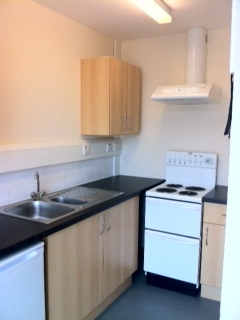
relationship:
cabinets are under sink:
[47, 193, 142, 320] [1, 198, 82, 225]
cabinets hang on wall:
[80, 56, 141, 136] [1, 2, 115, 204]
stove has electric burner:
[143, 149, 219, 297] [157, 187, 178, 194]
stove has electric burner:
[143, 149, 219, 297] [166, 182, 184, 189]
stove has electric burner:
[143, 149, 219, 297] [185, 185, 205, 192]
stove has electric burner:
[143, 149, 219, 297] [180, 191, 198, 198]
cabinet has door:
[80, 56, 141, 136] [109, 57, 127, 137]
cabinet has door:
[80, 56, 141, 136] [126, 62, 142, 135]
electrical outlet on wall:
[106, 143, 114, 155] [1, 2, 115, 204]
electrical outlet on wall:
[83, 144, 91, 156] [1, 2, 115, 204]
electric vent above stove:
[150, 27, 222, 104] [143, 149, 219, 297]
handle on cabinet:
[122, 115, 128, 132] [80, 56, 141, 136]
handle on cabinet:
[126, 115, 133, 133] [80, 56, 141, 136]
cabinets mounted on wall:
[80, 56, 141, 136] [1, 2, 115, 204]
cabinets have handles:
[47, 193, 142, 320] [99, 211, 111, 235]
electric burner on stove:
[157, 187, 178, 194] [143, 149, 219, 297]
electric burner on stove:
[185, 185, 205, 192] [143, 149, 219, 297]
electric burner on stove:
[180, 191, 198, 198] [143, 149, 219, 297]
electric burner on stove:
[166, 182, 184, 189] [143, 149, 219, 297]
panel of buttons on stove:
[165, 151, 217, 170] [143, 149, 219, 297]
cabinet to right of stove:
[201, 184, 224, 304] [143, 149, 219, 297]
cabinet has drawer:
[201, 184, 224, 304] [203, 201, 227, 225]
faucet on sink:
[30, 171, 45, 201] [1, 198, 82, 225]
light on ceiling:
[133, 0, 173, 25] [32, 2, 232, 38]